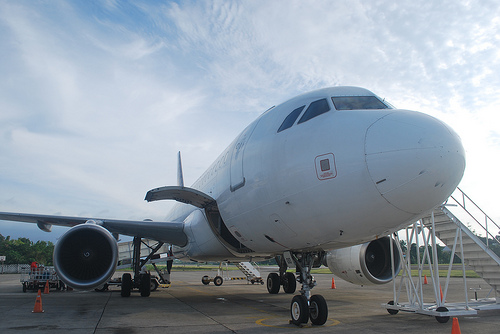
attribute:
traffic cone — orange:
[44, 280, 50, 293]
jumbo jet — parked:
[0, 84, 466, 323]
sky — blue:
[2, 3, 492, 123]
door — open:
[194, 80, 266, 221]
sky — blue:
[0, 0, 497, 239]